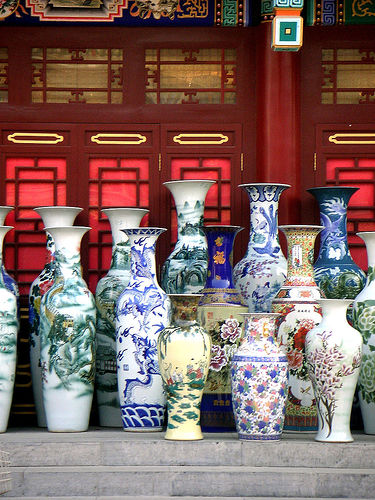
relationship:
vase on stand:
[113, 226, 172, 432] [3, 431, 374, 467]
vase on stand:
[113, 226, 172, 432] [1, 426, 373, 498]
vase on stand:
[159, 287, 213, 445] [30, 439, 131, 497]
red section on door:
[4, 155, 35, 179] [1, 118, 245, 429]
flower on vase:
[291, 324, 315, 352] [298, 167, 372, 300]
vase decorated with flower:
[226, 308, 291, 441] [243, 369, 253, 379]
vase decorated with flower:
[226, 308, 291, 441] [268, 369, 278, 379]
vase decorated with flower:
[226, 308, 291, 441] [238, 422, 246, 429]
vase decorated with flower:
[226, 308, 291, 441] [256, 420, 266, 429]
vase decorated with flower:
[226, 308, 291, 441] [272, 422, 280, 431]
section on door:
[89, 158, 116, 179] [78, 123, 157, 294]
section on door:
[89, 157, 150, 180] [79, 121, 163, 333]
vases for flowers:
[4, 177, 373, 443] [236, 365, 280, 440]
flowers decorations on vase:
[303, 331, 361, 437] [303, 296, 363, 443]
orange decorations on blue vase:
[271, 7, 310, 24] [195, 223, 249, 433]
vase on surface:
[305, 186, 367, 327] [2, 424, 374, 496]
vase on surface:
[232, 182, 293, 313] [2, 424, 374, 496]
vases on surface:
[163, 180, 212, 294] [2, 424, 374, 496]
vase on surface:
[156, 293, 212, 442] [2, 424, 374, 496]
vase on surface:
[229, 312, 290, 444] [2, 424, 374, 496]